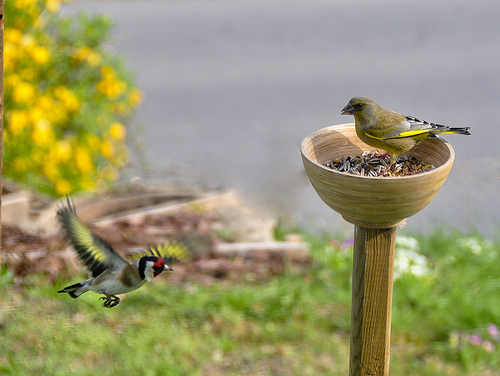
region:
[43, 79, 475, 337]
two goldfinch, male & female, i assume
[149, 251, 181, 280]
front of face is red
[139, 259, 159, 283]
middle of face is white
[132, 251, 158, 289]
back of head is black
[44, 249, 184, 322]
body is largely brown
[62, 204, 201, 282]
except for yellow interspersed wingfeathers.....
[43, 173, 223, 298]
.....amid & beneath the black wingfeathers with white polka dots!!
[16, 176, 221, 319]
i assume this is the male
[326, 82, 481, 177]
this is either the female or a juvenile; the red feathers show up only after 1st moult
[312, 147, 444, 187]
someone who isnt a bird stuck some seeds & corn, i think, in a bowl, & stuck the bowl on a pole, & here we are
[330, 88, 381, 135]
the head of a bird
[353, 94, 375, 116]
the eye of a bird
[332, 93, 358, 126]
the beak of a bird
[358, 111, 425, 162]
the wing of a bird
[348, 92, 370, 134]
the black eye of a bird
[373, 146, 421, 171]
the legs of a bird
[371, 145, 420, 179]
the feet of a bird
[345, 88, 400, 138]
the neck of a bird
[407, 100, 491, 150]
the tail of a bird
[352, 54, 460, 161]
the body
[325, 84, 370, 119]
head of a bird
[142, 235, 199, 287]
head of a bird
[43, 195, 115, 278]
wing of a bird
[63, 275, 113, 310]
tail of a bird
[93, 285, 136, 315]
leg of a bird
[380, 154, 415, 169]
leg of a bird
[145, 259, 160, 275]
eye of a bird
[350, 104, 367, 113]
eye of a bird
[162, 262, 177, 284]
peck of a bird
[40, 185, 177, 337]
the bird is flying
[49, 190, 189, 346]
the bird is flying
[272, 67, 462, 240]
bird in a wooden bowl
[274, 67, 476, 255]
bird in a wooden bowl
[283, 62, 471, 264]
bird in a wooden bowl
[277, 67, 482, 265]
bird in a wooden bowl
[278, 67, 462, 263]
bird in a wooden bowl